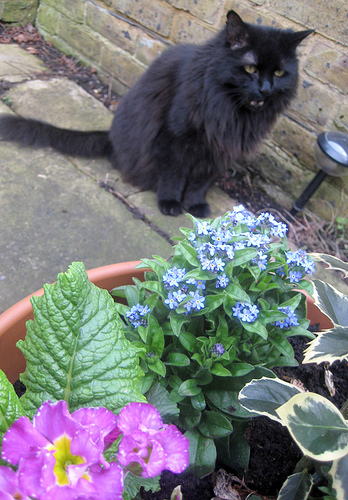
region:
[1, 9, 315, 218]
a black cat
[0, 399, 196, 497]
bright purple flowers with yellow interiors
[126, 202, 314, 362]
tiny blue and yellow flowers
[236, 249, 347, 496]
green leaves with white borders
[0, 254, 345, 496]
a flower pot full with plants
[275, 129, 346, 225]
a solar powered outdoor light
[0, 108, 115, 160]
the tail of a black cat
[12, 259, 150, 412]
a large green leaf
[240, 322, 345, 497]
soil in a brown flowerpot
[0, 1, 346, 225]
a brick wall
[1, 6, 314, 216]
black cat sitting on brick patio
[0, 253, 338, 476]
flower pot full of flowers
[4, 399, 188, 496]
pink flowers with yellow center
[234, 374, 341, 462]
dark green plant with white trim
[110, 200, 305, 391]
green plant with blue flowers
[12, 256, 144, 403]
dark green leaf in flower pot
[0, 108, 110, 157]
tail of black cat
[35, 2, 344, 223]
light colored brick wall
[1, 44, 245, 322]
light colored patio bricks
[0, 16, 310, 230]
stones inbetween wall and brick patio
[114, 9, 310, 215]
A black long haired cat.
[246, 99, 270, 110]
Bell on the cat's collar.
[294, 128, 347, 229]
Solar powered yard light.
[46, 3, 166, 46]
Tan colored brick wall.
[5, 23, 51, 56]
Leaves and dirt in a corner.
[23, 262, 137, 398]
Big green leaf of a plant.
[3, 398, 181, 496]
Purple flowers with yellow centers.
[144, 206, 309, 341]
Clusters of small blue flowers.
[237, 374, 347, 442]
Green leaves with white edges.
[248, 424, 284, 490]
Dark brown potting soil.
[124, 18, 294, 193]
The cat is black and scary.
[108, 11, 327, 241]
The black cat is standing by the wall.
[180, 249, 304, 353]
Blue flowers in the pot.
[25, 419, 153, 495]
Purple flower with yellow in the middle.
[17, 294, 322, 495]
A flower pot sitting on the round.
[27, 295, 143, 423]
The green leaf is big.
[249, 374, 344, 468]
The leaves is mixed with yellow.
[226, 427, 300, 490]
Soil under the flowers.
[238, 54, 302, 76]
The cat has green eyes.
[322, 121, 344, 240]
A light stick is in the ground.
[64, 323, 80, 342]
the color dark green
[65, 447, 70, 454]
this is the color yellow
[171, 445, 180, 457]
this is the color pink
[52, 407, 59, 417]
this is the color purple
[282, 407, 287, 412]
this is the color white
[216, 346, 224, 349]
this is the color blue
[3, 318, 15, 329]
this is the color brown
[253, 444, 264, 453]
this is the color black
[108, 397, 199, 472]
this is a purple flower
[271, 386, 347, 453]
a green and white leaf